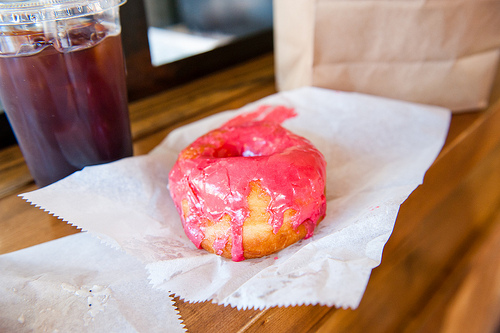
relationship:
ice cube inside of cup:
[61, 24, 99, 49] [2, 2, 137, 187]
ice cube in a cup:
[61, 24, 99, 49] [2, 2, 137, 187]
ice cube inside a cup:
[61, 24, 99, 49] [2, 2, 137, 187]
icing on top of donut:
[172, 119, 327, 258] [162, 122, 327, 264]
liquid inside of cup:
[2, 32, 134, 185] [2, 2, 137, 187]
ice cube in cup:
[61, 24, 99, 49] [2, 2, 137, 187]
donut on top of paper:
[162, 122, 327, 264] [18, 87, 455, 316]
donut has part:
[162, 122, 327, 264] [248, 214, 270, 241]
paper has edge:
[18, 87, 455, 316] [231, 299, 315, 318]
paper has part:
[18, 87, 455, 316] [346, 123, 382, 157]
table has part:
[0, 50, 499, 332] [444, 194, 463, 252]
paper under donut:
[18, 87, 455, 316] [162, 122, 327, 264]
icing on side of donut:
[172, 119, 327, 258] [162, 122, 327, 264]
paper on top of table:
[18, 87, 455, 316] [0, 50, 499, 332]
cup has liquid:
[2, 2, 137, 187] [2, 32, 134, 185]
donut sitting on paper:
[162, 122, 327, 264] [18, 87, 455, 316]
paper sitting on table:
[18, 87, 455, 316] [0, 50, 499, 332]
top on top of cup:
[2, 2, 129, 27] [2, 2, 137, 187]